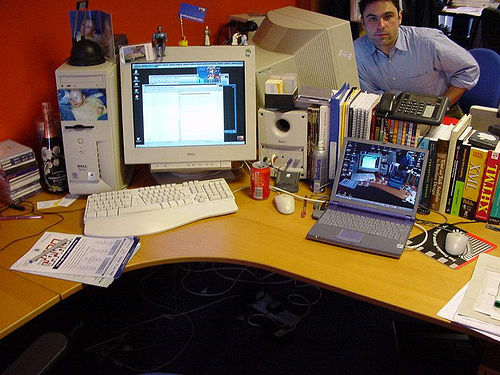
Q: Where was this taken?
A: An office.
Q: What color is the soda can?
A: Red.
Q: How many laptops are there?
A: One.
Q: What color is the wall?
A: Red.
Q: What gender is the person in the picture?
A: Male.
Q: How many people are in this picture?
A: One.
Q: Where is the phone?
A: On the books.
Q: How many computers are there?
A: Three.